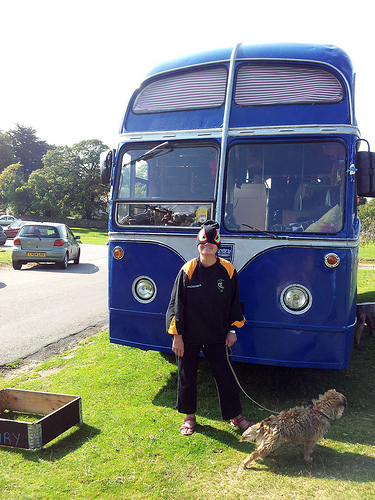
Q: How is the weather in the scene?
A: It is sunny.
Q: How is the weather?
A: It is sunny.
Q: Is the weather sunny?
A: Yes, it is sunny.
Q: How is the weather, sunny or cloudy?
A: It is sunny.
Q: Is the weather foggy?
A: No, it is sunny.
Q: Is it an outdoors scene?
A: Yes, it is outdoors.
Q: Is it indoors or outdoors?
A: It is outdoors.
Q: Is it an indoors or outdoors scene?
A: It is outdoors.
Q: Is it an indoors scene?
A: No, it is outdoors.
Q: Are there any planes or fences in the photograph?
A: No, there are no fences or planes.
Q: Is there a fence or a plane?
A: No, there are no fences or airplanes.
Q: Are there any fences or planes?
A: No, there are no fences or planes.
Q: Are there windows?
A: Yes, there is a window.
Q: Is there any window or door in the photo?
A: Yes, there is a window.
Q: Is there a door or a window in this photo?
A: Yes, there is a window.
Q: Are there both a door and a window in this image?
A: No, there is a window but no doors.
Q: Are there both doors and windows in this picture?
A: No, there is a window but no doors.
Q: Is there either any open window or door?
A: Yes, there is an open window.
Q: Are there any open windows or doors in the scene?
A: Yes, there is an open window.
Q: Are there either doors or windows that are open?
A: Yes, the window is open.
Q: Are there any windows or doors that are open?
A: Yes, the window is open.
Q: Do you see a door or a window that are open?
A: Yes, the window is open.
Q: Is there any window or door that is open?
A: Yes, the window is open.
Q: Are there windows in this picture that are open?
A: Yes, there is an open window.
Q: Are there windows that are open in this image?
A: Yes, there is an open window.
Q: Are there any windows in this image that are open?
A: Yes, there is an open window.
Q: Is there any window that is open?
A: Yes, there is a window that is open.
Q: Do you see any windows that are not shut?
A: Yes, there is a open window.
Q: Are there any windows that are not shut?
A: Yes, there is a open window.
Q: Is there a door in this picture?
A: No, there are no doors.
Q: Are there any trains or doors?
A: No, there are no doors or trains.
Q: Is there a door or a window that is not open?
A: No, there is a window but it is open.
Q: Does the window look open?
A: Yes, the window is open.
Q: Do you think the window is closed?
A: No, the window is open.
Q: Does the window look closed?
A: No, the window is open.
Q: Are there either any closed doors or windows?
A: No, there is a window but it is open.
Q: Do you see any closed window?
A: No, there is a window but it is open.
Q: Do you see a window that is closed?
A: No, there is a window but it is open.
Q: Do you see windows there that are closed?
A: No, there is a window but it is open.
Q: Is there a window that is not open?
A: No, there is a window but it is open.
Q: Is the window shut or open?
A: The window is open.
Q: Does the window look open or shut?
A: The window is open.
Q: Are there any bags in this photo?
A: No, there are no bags.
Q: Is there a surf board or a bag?
A: No, there are no bags or surfboards.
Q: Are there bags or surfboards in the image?
A: No, there are no bags or surfboards.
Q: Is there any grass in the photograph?
A: Yes, there is grass.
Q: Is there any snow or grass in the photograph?
A: Yes, there is grass.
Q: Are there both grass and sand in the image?
A: No, there is grass but no sand.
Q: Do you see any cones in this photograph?
A: No, there are no cones.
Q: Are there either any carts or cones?
A: No, there are no cones or carts.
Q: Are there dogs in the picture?
A: Yes, there is a dog.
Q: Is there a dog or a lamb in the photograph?
A: Yes, there is a dog.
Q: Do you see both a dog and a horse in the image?
A: No, there is a dog but no horses.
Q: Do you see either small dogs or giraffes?
A: Yes, there is a small dog.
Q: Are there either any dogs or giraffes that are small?
A: Yes, the dog is small.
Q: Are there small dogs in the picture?
A: Yes, there is a small dog.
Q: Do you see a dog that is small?
A: Yes, there is a small dog.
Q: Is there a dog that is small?
A: Yes, there is a dog that is small.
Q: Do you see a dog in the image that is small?
A: Yes, there is a dog that is small.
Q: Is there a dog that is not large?
A: Yes, there is a small dog.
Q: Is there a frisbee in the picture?
A: No, there are no frisbees.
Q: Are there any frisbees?
A: No, there are no frisbees.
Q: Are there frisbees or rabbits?
A: No, there are no frisbees or rabbits.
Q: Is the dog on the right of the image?
A: Yes, the dog is on the right of the image.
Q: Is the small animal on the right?
A: Yes, the dog is on the right of the image.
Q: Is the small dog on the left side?
A: No, the dog is on the right of the image.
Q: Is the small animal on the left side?
A: No, the dog is on the right of the image.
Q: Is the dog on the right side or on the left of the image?
A: The dog is on the right of the image.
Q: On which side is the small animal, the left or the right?
A: The dog is on the right of the image.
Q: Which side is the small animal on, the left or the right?
A: The dog is on the right of the image.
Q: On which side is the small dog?
A: The dog is on the right of the image.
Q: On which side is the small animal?
A: The dog is on the right of the image.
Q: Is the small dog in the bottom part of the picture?
A: Yes, the dog is in the bottom of the image.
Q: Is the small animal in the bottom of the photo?
A: Yes, the dog is in the bottom of the image.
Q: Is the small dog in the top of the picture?
A: No, the dog is in the bottom of the image.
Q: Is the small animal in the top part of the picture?
A: No, the dog is in the bottom of the image.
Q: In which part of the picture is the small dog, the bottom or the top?
A: The dog is in the bottom of the image.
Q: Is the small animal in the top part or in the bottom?
A: The dog is in the bottom of the image.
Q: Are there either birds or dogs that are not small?
A: No, there is a dog but it is small.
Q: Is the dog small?
A: Yes, the dog is small.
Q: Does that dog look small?
A: Yes, the dog is small.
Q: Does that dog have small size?
A: Yes, the dog is small.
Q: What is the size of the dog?
A: The dog is small.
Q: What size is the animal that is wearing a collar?
A: The dog is small.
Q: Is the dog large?
A: No, the dog is small.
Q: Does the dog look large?
A: No, the dog is small.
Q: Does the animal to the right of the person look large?
A: No, the dog is small.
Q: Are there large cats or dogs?
A: No, there is a dog but it is small.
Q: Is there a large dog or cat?
A: No, there is a dog but it is small.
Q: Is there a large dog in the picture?
A: No, there is a dog but it is small.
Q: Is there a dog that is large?
A: No, there is a dog but it is small.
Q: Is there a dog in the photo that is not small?
A: No, there is a dog but it is small.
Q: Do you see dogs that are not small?
A: No, there is a dog but it is small.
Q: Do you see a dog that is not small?
A: No, there is a dog but it is small.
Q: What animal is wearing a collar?
A: The dog is wearing a collar.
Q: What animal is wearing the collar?
A: The dog is wearing a collar.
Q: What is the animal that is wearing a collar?
A: The animal is a dog.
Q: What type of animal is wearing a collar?
A: The animal is a dog.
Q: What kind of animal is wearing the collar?
A: The animal is a dog.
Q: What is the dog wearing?
A: The dog is wearing a collar.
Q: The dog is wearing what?
A: The dog is wearing a collar.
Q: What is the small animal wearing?
A: The dog is wearing a collar.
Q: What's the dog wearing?
A: The dog is wearing a collar.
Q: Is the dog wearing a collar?
A: Yes, the dog is wearing a collar.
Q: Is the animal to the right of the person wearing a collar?
A: Yes, the dog is wearing a collar.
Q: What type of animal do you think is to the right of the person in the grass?
A: The animal is a dog.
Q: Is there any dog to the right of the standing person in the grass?
A: Yes, there is a dog to the right of the person.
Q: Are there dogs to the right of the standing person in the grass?
A: Yes, there is a dog to the right of the person.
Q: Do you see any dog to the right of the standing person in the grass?
A: Yes, there is a dog to the right of the person.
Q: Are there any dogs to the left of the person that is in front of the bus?
A: No, the dog is to the right of the person.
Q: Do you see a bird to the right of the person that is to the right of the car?
A: No, there is a dog to the right of the person.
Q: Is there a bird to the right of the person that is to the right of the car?
A: No, there is a dog to the right of the person.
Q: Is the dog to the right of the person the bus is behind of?
A: Yes, the dog is to the right of the person.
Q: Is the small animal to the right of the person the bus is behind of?
A: Yes, the dog is to the right of the person.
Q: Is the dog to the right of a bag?
A: No, the dog is to the right of the person.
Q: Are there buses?
A: Yes, there is a bus.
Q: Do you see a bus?
A: Yes, there is a bus.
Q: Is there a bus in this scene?
A: Yes, there is a bus.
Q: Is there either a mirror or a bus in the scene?
A: Yes, there is a bus.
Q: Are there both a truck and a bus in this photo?
A: No, there is a bus but no trucks.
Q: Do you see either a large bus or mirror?
A: Yes, there is a large bus.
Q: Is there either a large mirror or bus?
A: Yes, there is a large bus.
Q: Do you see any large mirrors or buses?
A: Yes, there is a large bus.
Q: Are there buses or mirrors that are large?
A: Yes, the bus is large.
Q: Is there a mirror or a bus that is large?
A: Yes, the bus is large.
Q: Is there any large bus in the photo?
A: Yes, there is a large bus.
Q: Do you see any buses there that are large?
A: Yes, there is a bus that is large.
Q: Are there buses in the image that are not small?
A: Yes, there is a large bus.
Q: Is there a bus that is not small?
A: Yes, there is a large bus.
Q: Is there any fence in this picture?
A: No, there are no fences.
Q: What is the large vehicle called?
A: The vehicle is a bus.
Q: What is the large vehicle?
A: The vehicle is a bus.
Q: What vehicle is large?
A: The vehicle is a bus.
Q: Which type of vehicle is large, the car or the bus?
A: The bus is large.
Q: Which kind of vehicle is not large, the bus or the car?
A: The car is not large.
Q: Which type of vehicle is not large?
A: The vehicle is a car.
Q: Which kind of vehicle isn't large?
A: The vehicle is a car.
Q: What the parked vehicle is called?
A: The vehicle is a bus.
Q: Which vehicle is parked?
A: The vehicle is a bus.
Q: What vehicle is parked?
A: The vehicle is a bus.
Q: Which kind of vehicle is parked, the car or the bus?
A: The bus is parked.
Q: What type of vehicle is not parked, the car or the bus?
A: The car is not parked.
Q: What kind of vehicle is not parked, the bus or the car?
A: The car is not parked.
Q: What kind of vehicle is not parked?
A: The vehicle is a car.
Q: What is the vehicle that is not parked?
A: The vehicle is a car.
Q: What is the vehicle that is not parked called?
A: The vehicle is a car.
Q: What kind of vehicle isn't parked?
A: The vehicle is a car.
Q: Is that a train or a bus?
A: That is a bus.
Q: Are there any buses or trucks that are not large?
A: No, there is a bus but it is large.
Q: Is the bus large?
A: Yes, the bus is large.